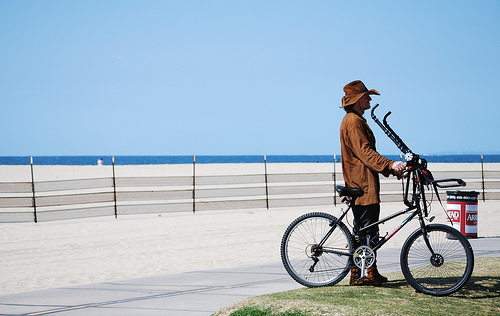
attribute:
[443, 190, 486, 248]
trash can — red, white, large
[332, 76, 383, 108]
hat — brown, floppy, covered, brow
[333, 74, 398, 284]
man — dressed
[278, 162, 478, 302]
bike — held, upright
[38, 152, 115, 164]
water — blue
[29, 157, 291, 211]
fence — see through, metal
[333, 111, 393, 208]
jacket — brown, long, brow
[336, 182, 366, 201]
seat — black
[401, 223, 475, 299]
tire — black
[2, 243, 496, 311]
trail — paved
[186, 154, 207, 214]
pole — metal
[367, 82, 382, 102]
brim — wide, floppy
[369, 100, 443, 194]
objects — long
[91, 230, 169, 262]
sand — white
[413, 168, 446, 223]
straps — assorted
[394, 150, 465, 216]
frames — assorted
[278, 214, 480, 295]
tires — black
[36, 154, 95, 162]
sea — blue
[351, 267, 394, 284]
shoes — brow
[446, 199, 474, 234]
drawig — red